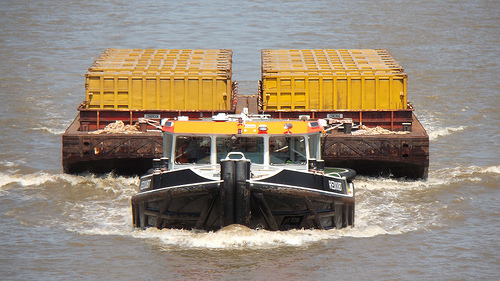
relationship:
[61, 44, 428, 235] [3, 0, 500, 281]
tugboat in water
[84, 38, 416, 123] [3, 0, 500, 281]
stuff in water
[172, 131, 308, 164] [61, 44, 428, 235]
windows of tugboat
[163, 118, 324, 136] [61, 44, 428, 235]
top of tugboat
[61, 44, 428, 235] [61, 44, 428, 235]
tugboat holding containers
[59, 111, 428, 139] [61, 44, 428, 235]
items in boat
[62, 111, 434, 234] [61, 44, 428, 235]
front of tugboat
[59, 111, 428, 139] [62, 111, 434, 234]
items in front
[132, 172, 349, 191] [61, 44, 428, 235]
writing on tugboat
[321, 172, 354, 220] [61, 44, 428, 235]
side of tugboat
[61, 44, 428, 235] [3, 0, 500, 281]
barge on ocean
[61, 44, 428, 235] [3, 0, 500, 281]
barge floating ocean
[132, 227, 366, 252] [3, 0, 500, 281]
waves in water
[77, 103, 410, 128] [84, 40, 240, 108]
supports under container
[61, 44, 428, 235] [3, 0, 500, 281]
lift in ocean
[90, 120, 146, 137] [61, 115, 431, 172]
rope on deck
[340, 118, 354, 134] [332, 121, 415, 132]
barrel on floor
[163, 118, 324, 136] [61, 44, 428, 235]
roof on tugboat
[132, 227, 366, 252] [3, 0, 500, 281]
whitecaps in ocean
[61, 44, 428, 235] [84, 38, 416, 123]
tow shipping containers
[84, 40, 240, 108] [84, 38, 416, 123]
yellow shipping containers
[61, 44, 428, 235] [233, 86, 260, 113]
barge main bridge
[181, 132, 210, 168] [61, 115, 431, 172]
person on deck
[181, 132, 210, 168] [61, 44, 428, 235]
person on tugboat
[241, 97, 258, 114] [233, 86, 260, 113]
post on bridge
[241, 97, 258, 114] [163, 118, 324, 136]
post on top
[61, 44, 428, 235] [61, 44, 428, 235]
barge style tugboat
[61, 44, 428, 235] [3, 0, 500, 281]
barge in water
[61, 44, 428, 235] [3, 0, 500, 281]
tugboat moving water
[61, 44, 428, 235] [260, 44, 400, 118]
tugboat pulling containers